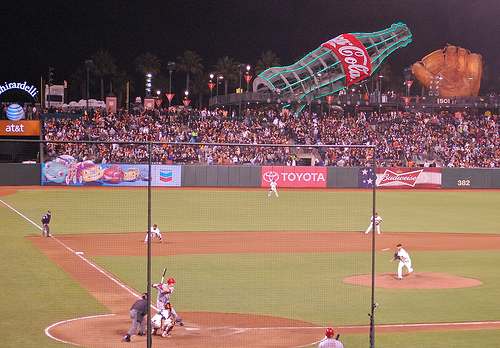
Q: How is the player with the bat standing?
A: Poised ready to hit the ball.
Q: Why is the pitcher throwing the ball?
A: So the batter can hit it.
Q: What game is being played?
A: Baseball.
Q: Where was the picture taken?
A: Baseball stadium.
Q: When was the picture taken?
A: During a baseball game.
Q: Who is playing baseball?
A: The players.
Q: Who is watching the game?
A: Spectators.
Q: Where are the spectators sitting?
A: In the stands.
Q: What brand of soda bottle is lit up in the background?
A: Coca-Cola.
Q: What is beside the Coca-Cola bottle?
A: Baseball mitt.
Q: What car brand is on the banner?
A: Toyota.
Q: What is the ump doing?
A: Watching.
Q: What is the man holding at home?
A: A bat.